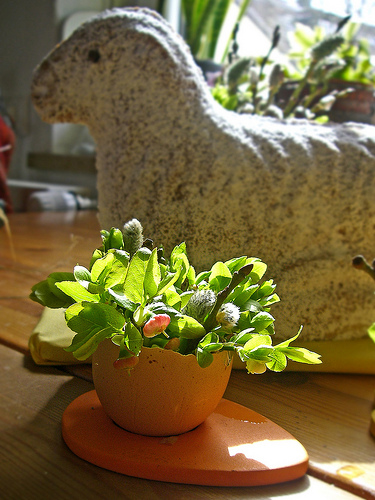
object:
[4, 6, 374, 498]
scene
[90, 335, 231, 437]
planter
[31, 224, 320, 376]
plants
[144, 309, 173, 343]
red blossom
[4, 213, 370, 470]
table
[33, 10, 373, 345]
sheep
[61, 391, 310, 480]
base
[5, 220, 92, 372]
counter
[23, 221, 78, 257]
glossy wood surface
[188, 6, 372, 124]
plants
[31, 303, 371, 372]
yellow base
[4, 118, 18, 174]
red towel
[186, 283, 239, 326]
flower buds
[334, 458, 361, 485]
water spot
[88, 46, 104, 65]
eye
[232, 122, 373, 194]
lines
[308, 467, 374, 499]
split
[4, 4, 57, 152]
wall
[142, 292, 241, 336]
flowers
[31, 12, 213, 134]
head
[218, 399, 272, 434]
water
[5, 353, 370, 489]
floor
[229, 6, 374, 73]
window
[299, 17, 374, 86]
plant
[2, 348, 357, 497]
board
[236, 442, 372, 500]
light